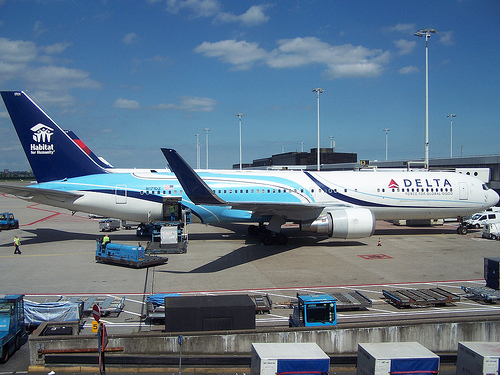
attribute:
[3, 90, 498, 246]
blue/white plane — white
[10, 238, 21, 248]
shirt — yellow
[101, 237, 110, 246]
shirt — yellow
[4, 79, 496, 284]
airplane — blue and white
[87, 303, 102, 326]
sign — round, red, white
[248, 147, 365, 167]
terminal roof — black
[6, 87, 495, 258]
airplane — blue, white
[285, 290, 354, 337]
truck — blue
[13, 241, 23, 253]
pants — black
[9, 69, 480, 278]
plane — blue